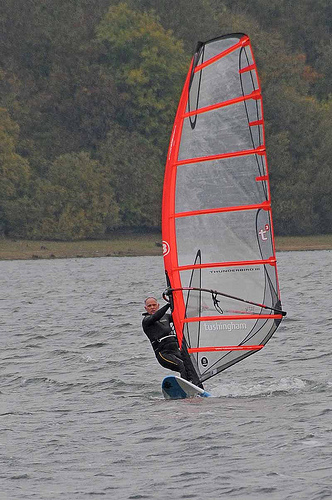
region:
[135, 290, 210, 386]
Man is wind surfing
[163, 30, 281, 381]
Sail is red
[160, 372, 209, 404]
Surfboard is blue and white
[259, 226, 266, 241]
Letter T on sail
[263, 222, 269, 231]
Number 3 above letter T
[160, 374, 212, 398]
Blue and whtie surfboard is wet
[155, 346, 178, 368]
Yellow stripe on pants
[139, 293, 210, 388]
Man holding on to sail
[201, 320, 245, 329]
Logo tushingham on sail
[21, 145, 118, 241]
Large green tree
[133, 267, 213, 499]
a man on a surf board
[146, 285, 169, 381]
a man wearing a black wet suit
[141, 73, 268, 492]
a surf board with a sail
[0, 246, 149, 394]
a body of water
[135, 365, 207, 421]
a blue and white surf board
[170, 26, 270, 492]
a red sail on a surf board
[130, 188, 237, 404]
a man on a surf board in the water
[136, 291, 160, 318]
a man with grey hair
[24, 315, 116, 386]
small waves in the water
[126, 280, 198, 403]
a man holding onto a sail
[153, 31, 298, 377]
The sail is clear and red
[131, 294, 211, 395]
The man is wearing a black wet suit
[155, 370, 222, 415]
The board is blue and white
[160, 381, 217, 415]
The board has stripes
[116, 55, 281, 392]
The man is wind surfing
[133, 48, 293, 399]
The man is standing on the board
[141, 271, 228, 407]
The man is holding onto the bar attached to the sail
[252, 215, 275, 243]
White and red letter t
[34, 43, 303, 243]
Dense foliage on shore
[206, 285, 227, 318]
The rope attached to the bar is black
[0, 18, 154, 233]
a bunch of green trees.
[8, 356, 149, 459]
a cold blue ocean.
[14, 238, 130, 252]
a view of short green grass.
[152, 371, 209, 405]
a blue and white surf board.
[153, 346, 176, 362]
a man is wearing black pants.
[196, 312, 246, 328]
the boat is a tushingham.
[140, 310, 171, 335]
a man is wearing a black shirt.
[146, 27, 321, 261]
a red black and grey wind surfer.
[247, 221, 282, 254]
the wind surfer says t3 on it.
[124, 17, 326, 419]
a man is surfing in the sea.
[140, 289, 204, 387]
Older man windsurfing in black wetsuit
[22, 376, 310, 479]
wind blown choppy water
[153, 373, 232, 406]
blue and white windsurfing board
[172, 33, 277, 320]
orange and black windsurfing sail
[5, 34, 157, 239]
dense foliage along rocky shore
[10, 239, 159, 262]
rocky grass covered shoreline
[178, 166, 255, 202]
clear panels in windsurfing sail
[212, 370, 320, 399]
light wake following windsurfer's path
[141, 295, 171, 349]
determined look on windsurfer's face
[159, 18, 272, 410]
Windsurfing board in clashing colors